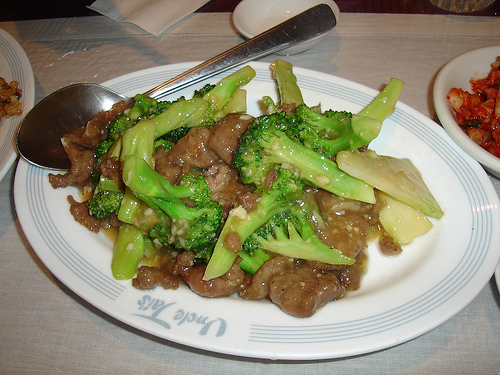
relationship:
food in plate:
[105, 79, 360, 281] [12, 58, 497, 362]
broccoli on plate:
[229, 111, 376, 203] [12, 58, 497, 362]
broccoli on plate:
[240, 218, 358, 269] [12, 58, 497, 362]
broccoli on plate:
[198, 161, 305, 281] [12, 58, 497, 362]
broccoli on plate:
[291, 103, 368, 157] [12, 58, 497, 362]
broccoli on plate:
[116, 149, 227, 250] [12, 58, 497, 362]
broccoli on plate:
[103, 96, 217, 139] [42, 70, 480, 340]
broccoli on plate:
[285, 102, 383, 159] [12, 58, 497, 362]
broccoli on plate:
[107, 93, 217, 139] [12, 58, 497, 362]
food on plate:
[447, 53, 497, 156] [2, 28, 35, 183]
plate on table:
[29, 23, 484, 368] [31, 24, 479, 347]